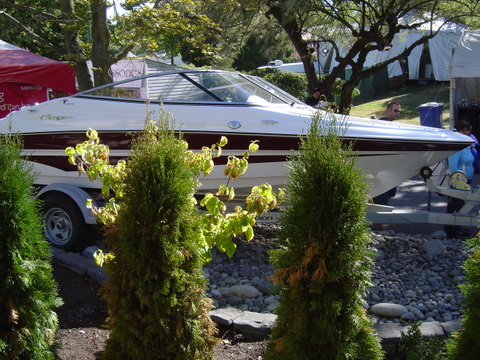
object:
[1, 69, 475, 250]
boat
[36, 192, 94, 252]
wheel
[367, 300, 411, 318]
rocks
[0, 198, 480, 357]
driveway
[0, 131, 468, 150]
stripe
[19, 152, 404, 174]
stripe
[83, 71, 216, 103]
window